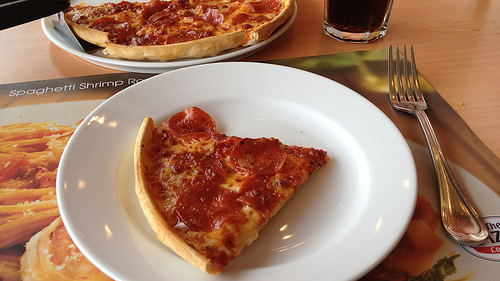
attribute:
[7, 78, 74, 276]
mat — here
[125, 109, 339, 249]
pizza — cut, sliced, here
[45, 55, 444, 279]
plate — round, white, here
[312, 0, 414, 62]
glass — here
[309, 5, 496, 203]
table — here, wood, wooden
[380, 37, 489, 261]
fork — sivler, here, gray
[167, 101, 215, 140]
pepperoni — sliced, red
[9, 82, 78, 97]
word — white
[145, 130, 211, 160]
cheese — melted